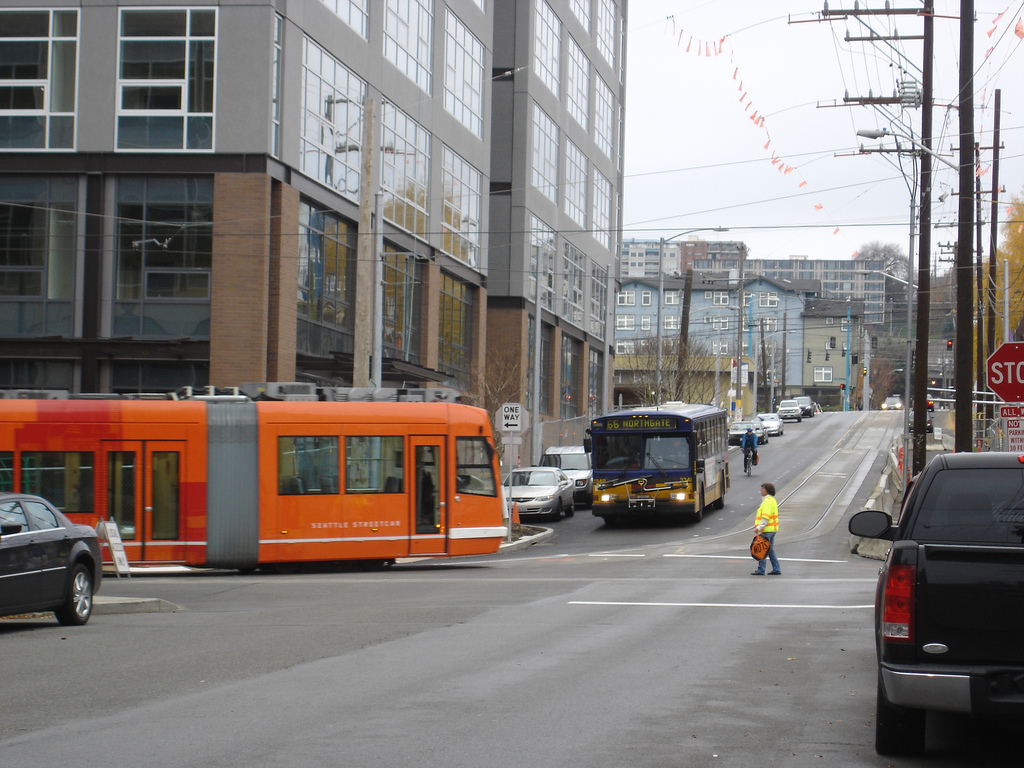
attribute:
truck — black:
[840, 440, 1022, 767]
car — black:
[2, 473, 121, 625]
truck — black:
[849, 448, 1015, 765]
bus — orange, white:
[14, 376, 520, 574]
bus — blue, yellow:
[578, 401, 732, 530]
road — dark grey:
[519, 623, 739, 745]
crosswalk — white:
[578, 535, 788, 621]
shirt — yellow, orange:
[748, 490, 791, 537]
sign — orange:
[747, 526, 776, 560]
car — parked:
[507, 454, 569, 524]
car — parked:
[538, 444, 597, 493]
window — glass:
[115, 81, 186, 119]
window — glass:
[115, 9, 198, 35]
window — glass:
[187, 5, 222, 37]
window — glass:
[187, 108, 222, 157]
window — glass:
[38, 34, 88, 115]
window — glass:
[47, 4, 87, 44]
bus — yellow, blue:
[567, 376, 736, 536]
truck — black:
[0, 402, 929, 765]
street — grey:
[1, 396, 913, 764]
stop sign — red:
[982, 335, 1022, 413]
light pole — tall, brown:
[951, 3, 977, 451]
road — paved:
[3, 407, 907, 766]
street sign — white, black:
[496, 399, 523, 432]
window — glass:
[267, 431, 347, 501]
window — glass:
[340, 427, 405, 497]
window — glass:
[452, 431, 500, 501]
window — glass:
[148, 440, 185, 536]